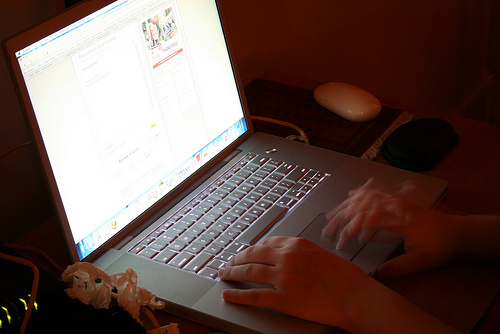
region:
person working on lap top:
[29, 20, 438, 305]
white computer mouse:
[305, 69, 375, 129]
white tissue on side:
[58, 248, 169, 319]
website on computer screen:
[24, 0, 223, 252]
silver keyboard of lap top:
[148, 153, 395, 295]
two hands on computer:
[224, 172, 419, 317]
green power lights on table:
[0, 277, 72, 331]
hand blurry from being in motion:
[322, 174, 443, 262]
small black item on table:
[385, 110, 459, 170]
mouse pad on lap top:
[292, 200, 372, 261]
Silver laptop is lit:
[8, 0, 446, 331]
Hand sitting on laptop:
[215, 233, 460, 330]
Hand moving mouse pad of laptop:
[322, 180, 499, 276]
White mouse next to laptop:
[312, 83, 382, 122]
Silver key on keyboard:
[197, 261, 219, 280]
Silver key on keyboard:
[184, 248, 213, 274]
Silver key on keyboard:
[235, 200, 288, 246]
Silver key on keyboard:
[285, 163, 308, 183]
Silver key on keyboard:
[139, 243, 156, 258]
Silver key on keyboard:
[178, 230, 195, 244]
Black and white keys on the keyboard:
[129, 239, 153, 264]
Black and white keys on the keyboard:
[148, 241, 194, 278]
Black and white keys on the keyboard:
[185, 246, 217, 276]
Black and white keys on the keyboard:
[153, 216, 196, 242]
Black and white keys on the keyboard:
[201, 236, 235, 268]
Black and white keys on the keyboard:
[190, 190, 218, 212]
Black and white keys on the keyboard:
[201, 198, 233, 233]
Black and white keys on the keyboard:
[233, 175, 267, 219]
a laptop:
[81, 42, 237, 254]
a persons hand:
[222, 236, 351, 314]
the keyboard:
[167, 200, 282, 222]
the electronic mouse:
[310, 228, 327, 240]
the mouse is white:
[311, 81, 381, 115]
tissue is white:
[68, 269, 145, 311]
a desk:
[461, 149, 493, 181]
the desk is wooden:
[449, 158, 492, 195]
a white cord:
[22, 275, 38, 300]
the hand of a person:
[213, 216, 334, 306]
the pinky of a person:
[214, 276, 313, 317]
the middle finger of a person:
[210, 250, 300, 265]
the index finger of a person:
[244, 226, 295, 258]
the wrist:
[314, 216, 409, 317]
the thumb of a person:
[363, 220, 473, 292]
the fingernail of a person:
[216, 285, 239, 305]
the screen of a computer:
[53, 20, 264, 242]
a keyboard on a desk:
[151, 99, 393, 283]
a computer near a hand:
[47, 12, 425, 319]